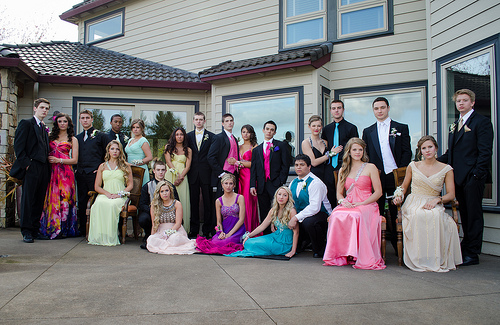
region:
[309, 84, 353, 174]
a guy with a blue tie on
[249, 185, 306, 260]
a girl with a blue dress on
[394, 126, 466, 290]
a girl with a white dress on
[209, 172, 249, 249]
a girl with a purple dress on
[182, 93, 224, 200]
a guy with a yellow bow tie on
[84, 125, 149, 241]
a girl sitting in a chair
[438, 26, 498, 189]
a boy standing by a window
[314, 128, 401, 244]
a girl with a pink dress on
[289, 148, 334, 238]
a guy with a blue vest on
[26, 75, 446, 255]
a group of people posing for a picture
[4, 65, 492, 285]
teens posing for picture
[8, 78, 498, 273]
teens wearing formal attire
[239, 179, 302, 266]
girl wearing a formal dress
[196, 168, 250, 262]
girl wearing a formal dress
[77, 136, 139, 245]
girl wearing a formal dress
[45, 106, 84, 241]
girl wearing a formal dress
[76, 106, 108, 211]
boy wearing a tuxedo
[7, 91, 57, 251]
boy wearing a tuxedo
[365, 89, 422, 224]
boy wearing a tuxedo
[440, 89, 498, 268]
boy wearing a tuxedo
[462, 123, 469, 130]
yellow pocket square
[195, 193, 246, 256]
purple dress on young woman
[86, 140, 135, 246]
woman in yellow dress sitting in chair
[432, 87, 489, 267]
young man standing at edge of group next to window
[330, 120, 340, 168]
blue neck tie on young man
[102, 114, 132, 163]
black man standing with group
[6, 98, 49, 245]
young man standing at edge of group in front of plant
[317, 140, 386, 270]
young woman in light pink dress sitting in chair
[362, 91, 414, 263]
man in white shirt and white tie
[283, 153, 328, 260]
young man in blue vest and blue tie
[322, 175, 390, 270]
the girl is wearing a gown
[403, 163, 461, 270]
the girl is wearing a gown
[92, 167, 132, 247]
the girl is wearing a gown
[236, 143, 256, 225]
the girl is wearing a gown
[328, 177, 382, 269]
the gown is light red in color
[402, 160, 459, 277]
the gown is yellow in color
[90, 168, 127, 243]
the gown is green in color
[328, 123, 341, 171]
the man is wearing a tie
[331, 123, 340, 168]
the tie is blue in color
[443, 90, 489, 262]
the man is standing still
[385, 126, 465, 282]
person in a wedding party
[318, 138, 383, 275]
person in a wedding party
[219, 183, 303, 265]
person in a wedding party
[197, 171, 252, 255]
person in a wedding party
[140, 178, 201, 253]
person in a wedding party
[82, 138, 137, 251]
person in a wedding party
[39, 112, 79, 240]
person in a wedding party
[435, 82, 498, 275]
person in a wedding party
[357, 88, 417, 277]
person in a wedding party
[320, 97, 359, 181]
person in a wedding party